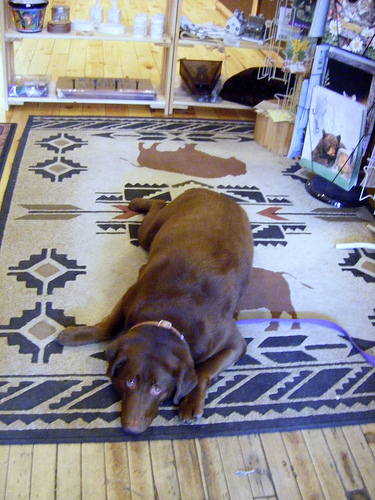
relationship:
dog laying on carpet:
[55, 188, 254, 436] [13, 106, 363, 431]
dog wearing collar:
[55, 188, 254, 436] [127, 320, 191, 343]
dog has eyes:
[55, 188, 254, 436] [123, 363, 170, 399]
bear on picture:
[309, 126, 344, 168] [297, 83, 368, 191]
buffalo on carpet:
[119, 138, 247, 179] [0, 112, 374, 446]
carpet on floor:
[18, 105, 171, 184] [60, 39, 141, 87]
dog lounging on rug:
[70, 143, 348, 403] [1, 114, 370, 439]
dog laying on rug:
[55, 188, 254, 436] [1, 114, 370, 439]